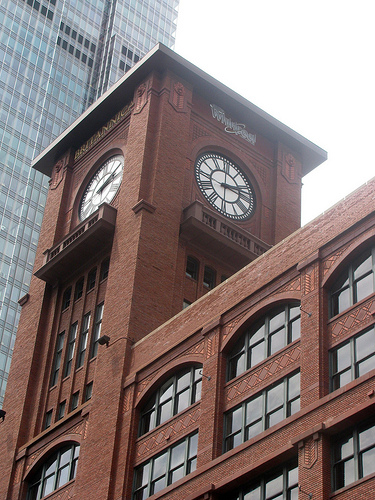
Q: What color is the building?
A: Red.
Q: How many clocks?
A: 1.